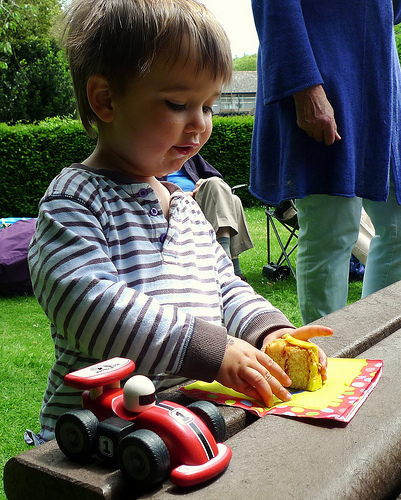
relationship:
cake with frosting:
[263, 333, 323, 391] [282, 332, 323, 388]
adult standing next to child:
[248, 2, 398, 326] [24, 0, 332, 449]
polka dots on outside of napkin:
[185, 386, 347, 440] [175, 355, 385, 429]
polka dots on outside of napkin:
[321, 352, 386, 421] [175, 355, 385, 429]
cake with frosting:
[253, 319, 340, 390] [277, 324, 318, 350]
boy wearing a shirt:
[25, 10, 336, 381] [28, 160, 300, 376]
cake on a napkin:
[265, 343, 330, 381] [255, 355, 374, 421]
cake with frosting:
[265, 333, 325, 387] [308, 342, 322, 386]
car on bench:
[59, 360, 238, 487] [337, 310, 394, 458]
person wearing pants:
[259, 3, 393, 312] [293, 191, 398, 302]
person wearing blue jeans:
[250, 1, 400, 328] [291, 192, 399, 320]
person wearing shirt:
[250, 1, 400, 328] [250, 1, 400, 205]